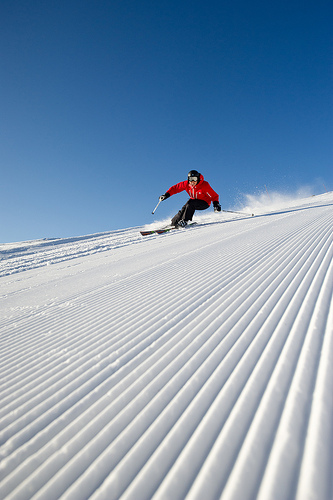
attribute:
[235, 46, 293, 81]
clouds — white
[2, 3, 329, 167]
sky — blue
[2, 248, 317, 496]
lines — deep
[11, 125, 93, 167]
clouds — white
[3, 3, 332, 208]
sky — blue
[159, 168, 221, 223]
skier — coming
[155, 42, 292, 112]
sky — cloudless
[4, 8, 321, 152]
sky — blue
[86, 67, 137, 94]
sky — blue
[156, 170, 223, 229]
skier — going down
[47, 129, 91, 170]
clouds — white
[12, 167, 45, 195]
clouds — white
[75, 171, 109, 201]
clouds — white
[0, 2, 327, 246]
sky — cloudless, blue